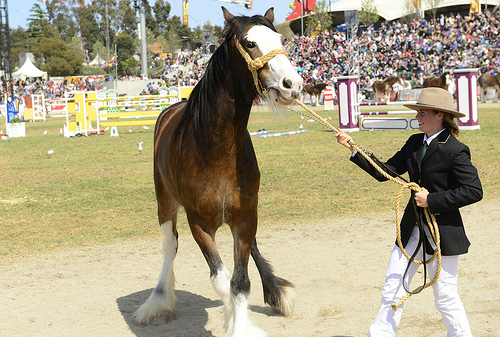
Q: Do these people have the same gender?
A: No, they are both male and female.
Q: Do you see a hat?
A: Yes, there is a hat.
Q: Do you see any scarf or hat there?
A: Yes, there is a hat.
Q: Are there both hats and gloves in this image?
A: No, there is a hat but no gloves.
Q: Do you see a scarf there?
A: No, there are no scarves.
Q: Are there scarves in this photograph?
A: No, there are no scarves.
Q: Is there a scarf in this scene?
A: No, there are no scarves.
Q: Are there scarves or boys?
A: No, there are no scarves or boys.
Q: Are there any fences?
A: Yes, there is a fence.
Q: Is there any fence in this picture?
A: Yes, there is a fence.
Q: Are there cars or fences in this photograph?
A: Yes, there is a fence.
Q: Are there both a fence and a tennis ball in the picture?
A: No, there is a fence but no tennis balls.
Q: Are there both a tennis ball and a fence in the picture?
A: No, there is a fence but no tennis balls.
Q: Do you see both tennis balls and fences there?
A: No, there is a fence but no tennis balls.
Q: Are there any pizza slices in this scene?
A: No, there are no pizza slices.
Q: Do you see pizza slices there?
A: No, there are no pizza slices.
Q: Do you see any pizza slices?
A: No, there are no pizza slices.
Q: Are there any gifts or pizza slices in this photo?
A: No, there are no pizza slices or gifts.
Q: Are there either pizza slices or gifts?
A: No, there are no pizza slices or gifts.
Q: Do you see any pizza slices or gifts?
A: No, there are no pizza slices or gifts.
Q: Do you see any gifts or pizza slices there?
A: No, there are no pizza slices or gifts.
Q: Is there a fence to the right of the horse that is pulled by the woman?
A: Yes, there is a fence to the right of the horse.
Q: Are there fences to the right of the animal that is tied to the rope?
A: Yes, there is a fence to the right of the horse.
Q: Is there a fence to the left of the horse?
A: No, the fence is to the right of the horse.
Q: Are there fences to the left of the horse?
A: No, the fence is to the right of the horse.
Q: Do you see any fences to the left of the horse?
A: No, the fence is to the right of the horse.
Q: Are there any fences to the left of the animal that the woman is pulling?
A: No, the fence is to the right of the horse.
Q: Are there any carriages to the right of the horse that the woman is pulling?
A: No, there is a fence to the right of the horse.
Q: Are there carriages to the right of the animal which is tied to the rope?
A: No, there is a fence to the right of the horse.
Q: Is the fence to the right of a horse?
A: Yes, the fence is to the right of a horse.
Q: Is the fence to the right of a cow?
A: No, the fence is to the right of a horse.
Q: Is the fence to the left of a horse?
A: No, the fence is to the right of a horse.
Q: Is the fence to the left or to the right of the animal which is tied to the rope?
A: The fence is to the right of the horse.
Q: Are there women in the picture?
A: Yes, there is a woman.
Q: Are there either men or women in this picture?
A: Yes, there is a woman.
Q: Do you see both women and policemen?
A: No, there is a woman but no policemen.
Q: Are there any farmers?
A: No, there are no farmers.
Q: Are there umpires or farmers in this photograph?
A: No, there are no farmers or umpires.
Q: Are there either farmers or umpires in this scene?
A: No, there are no farmers or umpires.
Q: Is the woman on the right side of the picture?
A: Yes, the woman is on the right of the image.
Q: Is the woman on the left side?
A: No, the woman is on the right of the image.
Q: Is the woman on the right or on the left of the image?
A: The woman is on the right of the image.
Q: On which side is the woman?
A: The woman is on the right of the image.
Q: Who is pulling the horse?
A: The woman is pulling the horse.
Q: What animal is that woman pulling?
A: The woman is pulling the horse.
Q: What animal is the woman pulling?
A: The woman is pulling the horse.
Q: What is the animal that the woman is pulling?
A: The animal is a horse.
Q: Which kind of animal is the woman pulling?
A: The woman is pulling the horse.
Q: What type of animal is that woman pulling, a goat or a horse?
A: The woman is pulling a horse.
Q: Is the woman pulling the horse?
A: Yes, the woman is pulling the horse.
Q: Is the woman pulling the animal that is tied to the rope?
A: Yes, the woman is pulling the horse.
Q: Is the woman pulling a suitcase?
A: No, the woman is pulling the horse.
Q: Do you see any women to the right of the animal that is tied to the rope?
A: Yes, there is a woman to the right of the horse.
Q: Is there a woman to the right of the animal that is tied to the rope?
A: Yes, there is a woman to the right of the horse.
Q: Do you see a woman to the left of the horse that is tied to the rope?
A: No, the woman is to the right of the horse.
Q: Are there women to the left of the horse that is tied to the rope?
A: No, the woman is to the right of the horse.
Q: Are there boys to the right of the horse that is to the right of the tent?
A: No, there is a woman to the right of the horse.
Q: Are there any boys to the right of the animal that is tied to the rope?
A: No, there is a woman to the right of the horse.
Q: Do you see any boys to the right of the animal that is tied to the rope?
A: No, there is a woman to the right of the horse.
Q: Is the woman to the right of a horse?
A: Yes, the woman is to the right of a horse.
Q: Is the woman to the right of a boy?
A: No, the woman is to the right of a horse.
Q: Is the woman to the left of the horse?
A: No, the woman is to the right of the horse.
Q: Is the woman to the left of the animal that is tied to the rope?
A: No, the woman is to the right of the horse.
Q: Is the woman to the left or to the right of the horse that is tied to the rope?
A: The woman is to the right of the horse.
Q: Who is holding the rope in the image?
A: The woman is holding the rope.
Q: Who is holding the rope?
A: The woman is holding the rope.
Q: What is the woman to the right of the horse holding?
A: The woman is holding the rope.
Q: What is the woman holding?
A: The woman is holding the rope.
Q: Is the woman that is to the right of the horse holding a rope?
A: Yes, the woman is holding a rope.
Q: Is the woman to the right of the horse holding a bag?
A: No, the woman is holding a rope.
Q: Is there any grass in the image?
A: Yes, there is grass.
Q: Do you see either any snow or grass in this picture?
A: Yes, there is grass.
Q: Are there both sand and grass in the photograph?
A: Yes, there are both grass and sand.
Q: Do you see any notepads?
A: No, there are no notepads.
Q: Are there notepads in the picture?
A: No, there are no notepads.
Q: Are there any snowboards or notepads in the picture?
A: No, there are no notepads or snowboards.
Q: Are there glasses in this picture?
A: No, there are no glasses.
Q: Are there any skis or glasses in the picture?
A: No, there are no glasses or skis.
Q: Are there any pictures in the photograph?
A: No, there are no pictures.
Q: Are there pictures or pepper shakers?
A: No, there are no pictures or pepper shakers.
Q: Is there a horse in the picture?
A: Yes, there is a horse.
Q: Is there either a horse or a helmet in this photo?
A: Yes, there is a horse.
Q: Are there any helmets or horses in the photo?
A: Yes, there is a horse.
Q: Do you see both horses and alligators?
A: No, there is a horse but no alligators.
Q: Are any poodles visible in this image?
A: No, there are no poodles.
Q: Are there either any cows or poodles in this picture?
A: No, there are no poodles or cows.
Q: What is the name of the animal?
A: The animal is a horse.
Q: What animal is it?
A: The animal is a horse.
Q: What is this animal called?
A: This is a horse.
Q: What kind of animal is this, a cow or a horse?
A: This is a horse.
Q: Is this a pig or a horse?
A: This is a horse.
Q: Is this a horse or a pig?
A: This is a horse.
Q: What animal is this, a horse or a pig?
A: This is a horse.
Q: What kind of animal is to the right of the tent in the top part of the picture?
A: The animal is a horse.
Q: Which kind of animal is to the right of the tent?
A: The animal is a horse.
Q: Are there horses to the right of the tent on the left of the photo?
A: Yes, there is a horse to the right of the tent.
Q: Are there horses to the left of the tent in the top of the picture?
A: No, the horse is to the right of the tent.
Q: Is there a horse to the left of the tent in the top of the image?
A: No, the horse is to the right of the tent.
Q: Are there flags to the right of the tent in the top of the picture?
A: No, there is a horse to the right of the tent.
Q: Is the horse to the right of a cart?
A: No, the horse is to the right of the tent.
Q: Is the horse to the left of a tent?
A: No, the horse is to the right of a tent.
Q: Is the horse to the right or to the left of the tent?
A: The horse is to the right of the tent.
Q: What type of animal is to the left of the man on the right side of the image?
A: The animal is a horse.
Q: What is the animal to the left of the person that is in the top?
A: The animal is a horse.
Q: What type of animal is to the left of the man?
A: The animal is a horse.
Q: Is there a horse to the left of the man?
A: Yes, there is a horse to the left of the man.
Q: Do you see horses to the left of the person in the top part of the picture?
A: Yes, there is a horse to the left of the man.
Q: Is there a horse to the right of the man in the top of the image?
A: No, the horse is to the left of the man.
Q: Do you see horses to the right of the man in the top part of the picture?
A: No, the horse is to the left of the man.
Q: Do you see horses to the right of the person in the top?
A: No, the horse is to the left of the man.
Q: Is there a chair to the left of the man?
A: No, there is a horse to the left of the man.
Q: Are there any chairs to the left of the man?
A: No, there is a horse to the left of the man.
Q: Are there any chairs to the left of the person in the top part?
A: No, there is a horse to the left of the man.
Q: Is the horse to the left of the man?
A: Yes, the horse is to the left of the man.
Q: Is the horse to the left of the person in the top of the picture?
A: Yes, the horse is to the left of the man.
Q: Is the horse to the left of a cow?
A: No, the horse is to the left of the man.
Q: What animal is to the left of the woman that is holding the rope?
A: The animal is a horse.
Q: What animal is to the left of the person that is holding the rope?
A: The animal is a horse.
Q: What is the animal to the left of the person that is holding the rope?
A: The animal is a horse.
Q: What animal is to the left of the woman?
A: The animal is a horse.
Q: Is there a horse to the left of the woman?
A: Yes, there is a horse to the left of the woman.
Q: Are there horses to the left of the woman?
A: Yes, there is a horse to the left of the woman.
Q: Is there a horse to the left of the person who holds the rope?
A: Yes, there is a horse to the left of the woman.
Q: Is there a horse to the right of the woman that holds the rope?
A: No, the horse is to the left of the woman.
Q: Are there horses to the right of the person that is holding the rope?
A: No, the horse is to the left of the woman.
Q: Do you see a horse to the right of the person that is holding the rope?
A: No, the horse is to the left of the woman.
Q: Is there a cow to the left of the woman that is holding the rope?
A: No, there is a horse to the left of the woman.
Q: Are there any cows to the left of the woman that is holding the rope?
A: No, there is a horse to the left of the woman.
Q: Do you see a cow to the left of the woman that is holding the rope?
A: No, there is a horse to the left of the woman.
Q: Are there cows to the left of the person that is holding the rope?
A: No, there is a horse to the left of the woman.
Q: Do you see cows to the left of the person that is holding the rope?
A: No, there is a horse to the left of the woman.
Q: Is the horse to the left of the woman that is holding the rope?
A: Yes, the horse is to the left of the woman.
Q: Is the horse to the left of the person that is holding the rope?
A: Yes, the horse is to the left of the woman.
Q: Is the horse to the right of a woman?
A: No, the horse is to the left of a woman.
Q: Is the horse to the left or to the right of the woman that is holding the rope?
A: The horse is to the left of the woman.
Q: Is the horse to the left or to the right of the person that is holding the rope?
A: The horse is to the left of the woman.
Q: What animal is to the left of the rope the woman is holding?
A: The animal is a horse.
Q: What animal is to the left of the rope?
A: The animal is a horse.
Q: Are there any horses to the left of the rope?
A: Yes, there is a horse to the left of the rope.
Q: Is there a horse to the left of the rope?
A: Yes, there is a horse to the left of the rope.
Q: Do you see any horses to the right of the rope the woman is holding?
A: No, the horse is to the left of the rope.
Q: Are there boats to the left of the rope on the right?
A: No, there is a horse to the left of the rope.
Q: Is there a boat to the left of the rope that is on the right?
A: No, there is a horse to the left of the rope.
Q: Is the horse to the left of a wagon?
A: No, the horse is to the left of the rope.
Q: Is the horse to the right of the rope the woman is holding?
A: No, the horse is to the left of the rope.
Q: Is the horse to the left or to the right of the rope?
A: The horse is to the left of the rope.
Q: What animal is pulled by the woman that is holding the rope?
A: The horse is pulled by the woman.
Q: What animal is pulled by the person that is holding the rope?
A: The horse is pulled by the woman.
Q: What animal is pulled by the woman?
A: The horse is pulled by the woman.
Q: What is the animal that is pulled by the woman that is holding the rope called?
A: The animal is a horse.